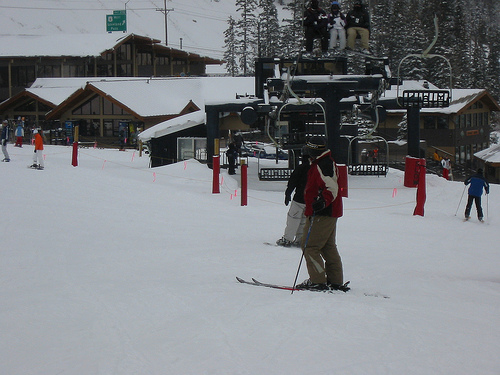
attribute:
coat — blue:
[468, 183, 490, 198]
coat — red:
[307, 168, 331, 192]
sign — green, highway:
[104, 14, 133, 27]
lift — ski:
[253, 108, 321, 174]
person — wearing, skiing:
[236, 138, 340, 220]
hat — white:
[300, 133, 326, 152]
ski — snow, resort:
[237, 220, 308, 253]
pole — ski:
[268, 205, 317, 305]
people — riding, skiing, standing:
[267, 7, 378, 52]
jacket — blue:
[464, 179, 479, 192]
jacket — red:
[310, 158, 339, 215]